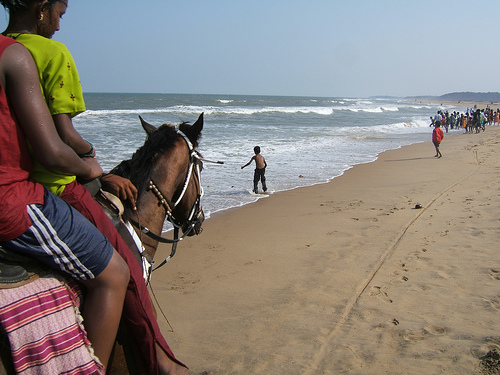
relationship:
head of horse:
[140, 113, 212, 240] [0, 110, 204, 373]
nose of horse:
[192, 212, 208, 233] [34, 103, 212, 373]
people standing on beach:
[424, 96, 496, 160] [134, 125, 499, 367]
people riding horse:
[0, 6, 138, 369] [0, 110, 204, 373]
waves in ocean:
[77, 100, 447, 142] [74, 93, 479, 238]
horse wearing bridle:
[0, 110, 204, 373] [152, 122, 207, 233]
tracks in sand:
[304, 180, 467, 373] [212, 161, 498, 372]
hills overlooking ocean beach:
[363, 89, 499, 105] [141, 98, 498, 372]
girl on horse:
[2, 1, 204, 371] [0, 106, 240, 373]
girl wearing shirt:
[2, 1, 204, 371] [10, 33, 102, 188]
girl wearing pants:
[2, 1, 204, 371] [52, 174, 196, 374]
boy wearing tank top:
[0, 36, 132, 373] [0, 33, 47, 245]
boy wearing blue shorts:
[0, 36, 132, 373] [2, 187, 120, 294]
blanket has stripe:
[1, 297, 75, 338] [0, 287, 79, 327]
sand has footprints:
[376, 210, 491, 365] [368, 170, 463, 358]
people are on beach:
[428, 106, 496, 136] [132, 106, 498, 361]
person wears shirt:
[2, 1, 97, 154] [1, 29, 85, 119]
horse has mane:
[0, 106, 240, 373] [86, 117, 208, 213]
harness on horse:
[160, 121, 206, 241] [0, 106, 240, 373]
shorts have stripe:
[3, 186, 114, 281] [28, 207, 90, 291]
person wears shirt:
[1, 9, 134, 372] [0, 36, 44, 239]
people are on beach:
[430, 120, 444, 157] [3, 100, 498, 374]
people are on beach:
[473, 109, 481, 132] [3, 100, 498, 374]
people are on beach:
[460, 112, 468, 134] [3, 100, 498, 374]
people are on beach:
[495, 107, 499, 125] [3, 100, 498, 374]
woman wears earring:
[426, 121, 450, 158] [32, 6, 52, 26]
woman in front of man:
[1, 4, 98, 113] [2, 42, 128, 277]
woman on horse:
[1, 4, 98, 113] [82, 100, 238, 284]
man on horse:
[2, 42, 128, 277] [82, 100, 238, 284]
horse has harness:
[63, 86, 252, 335] [107, 165, 199, 289]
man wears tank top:
[0, 2, 130, 368] [0, 33, 47, 245]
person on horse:
[2, 31, 129, 372] [117, 110, 207, 230]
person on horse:
[2, 1, 97, 154] [117, 110, 207, 230]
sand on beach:
[109, 96, 499, 373] [84, 95, 499, 374]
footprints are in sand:
[372, 259, 422, 297] [305, 219, 459, 358]